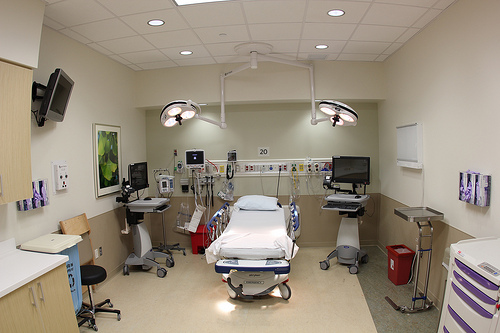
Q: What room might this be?
A: Hospital room.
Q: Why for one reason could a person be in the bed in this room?
A: They're ill.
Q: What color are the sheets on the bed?
A: White.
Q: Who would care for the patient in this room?
A: Doctor.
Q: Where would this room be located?
A: Hospital.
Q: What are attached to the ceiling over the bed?
A: Lights.